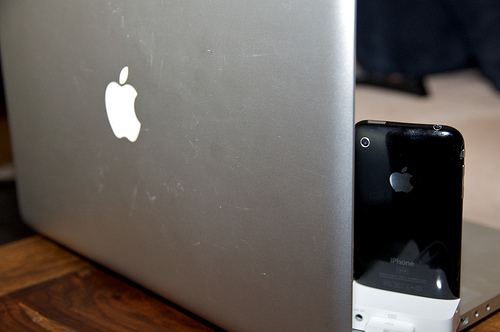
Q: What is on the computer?
A: Apple.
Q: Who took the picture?
A: Man.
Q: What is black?
A: Iphone.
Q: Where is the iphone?
A: To the right of the computer.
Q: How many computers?
A: One.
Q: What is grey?
A: Computer.